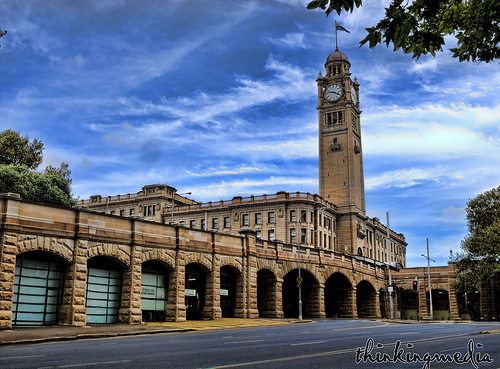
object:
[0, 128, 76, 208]
tree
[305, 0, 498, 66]
tree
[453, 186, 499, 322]
tree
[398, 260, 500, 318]
building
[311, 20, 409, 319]
building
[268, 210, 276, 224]
window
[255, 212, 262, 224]
window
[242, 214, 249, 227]
window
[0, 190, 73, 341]
building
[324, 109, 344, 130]
windows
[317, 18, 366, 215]
clock tower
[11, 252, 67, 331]
shutter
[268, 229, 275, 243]
window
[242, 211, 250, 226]
window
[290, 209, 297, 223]
window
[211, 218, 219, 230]
window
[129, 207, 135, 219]
window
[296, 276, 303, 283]
sign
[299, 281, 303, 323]
pole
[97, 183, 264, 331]
building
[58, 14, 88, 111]
sky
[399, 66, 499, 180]
sky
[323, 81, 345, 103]
clock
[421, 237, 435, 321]
light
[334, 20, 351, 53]
flag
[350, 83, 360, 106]
clock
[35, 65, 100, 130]
clouds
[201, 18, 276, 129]
sky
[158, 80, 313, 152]
cloud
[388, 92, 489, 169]
cloud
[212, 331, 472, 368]
line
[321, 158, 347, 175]
brick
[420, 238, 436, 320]
pole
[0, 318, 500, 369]
road